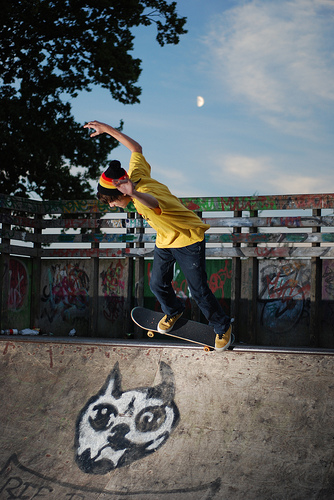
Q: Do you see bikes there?
A: No, there are no bikes.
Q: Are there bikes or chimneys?
A: No, there are no bikes or chimneys.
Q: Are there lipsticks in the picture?
A: No, there are no lipsticks.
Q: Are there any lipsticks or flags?
A: No, there are no lipsticks or flags.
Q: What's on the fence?
A: The graffiti is on the fence.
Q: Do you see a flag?
A: No, there are no flags.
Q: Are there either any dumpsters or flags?
A: No, there are no flags or dumpsters.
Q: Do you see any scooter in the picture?
A: No, there are no scooters.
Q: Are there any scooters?
A: No, there are no scooters.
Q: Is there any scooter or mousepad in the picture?
A: No, there are no scooters or mouse pads.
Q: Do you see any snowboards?
A: No, there are no snowboards.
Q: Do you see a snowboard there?
A: No, there are no snowboards.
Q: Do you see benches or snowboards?
A: No, there are no snowboards or benches.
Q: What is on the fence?
A: The graffiti is on the fence.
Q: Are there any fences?
A: Yes, there is a fence.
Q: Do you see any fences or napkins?
A: Yes, there is a fence.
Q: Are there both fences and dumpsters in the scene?
A: No, there is a fence but no dumpsters.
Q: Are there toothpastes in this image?
A: No, there are no toothpastes.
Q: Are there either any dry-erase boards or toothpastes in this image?
A: No, there are no toothpastes or dry-erase boards.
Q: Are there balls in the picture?
A: No, there are no balls.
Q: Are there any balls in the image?
A: No, there are no balls.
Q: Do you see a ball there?
A: No, there are no balls.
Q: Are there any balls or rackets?
A: No, there are no balls or rackets.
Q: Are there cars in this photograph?
A: No, there are no cars.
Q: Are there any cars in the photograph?
A: No, there are no cars.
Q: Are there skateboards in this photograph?
A: Yes, there is a skateboard.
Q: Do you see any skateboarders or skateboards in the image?
A: Yes, there is a skateboard.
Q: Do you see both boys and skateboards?
A: Yes, there are both a skateboard and a boy.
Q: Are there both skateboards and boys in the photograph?
A: Yes, there are both a skateboard and a boy.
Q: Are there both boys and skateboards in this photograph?
A: Yes, there are both a skateboard and a boy.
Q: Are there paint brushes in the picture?
A: No, there are no paint brushes.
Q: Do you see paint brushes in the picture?
A: No, there are no paint brushes.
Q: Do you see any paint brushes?
A: No, there are no paint brushes.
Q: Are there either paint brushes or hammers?
A: No, there are no paint brushes or hammers.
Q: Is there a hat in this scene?
A: Yes, there is a hat.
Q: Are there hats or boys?
A: Yes, there is a hat.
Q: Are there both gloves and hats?
A: No, there is a hat but no gloves.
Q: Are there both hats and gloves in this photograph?
A: No, there is a hat but no gloves.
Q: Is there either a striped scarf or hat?
A: Yes, there is a striped hat.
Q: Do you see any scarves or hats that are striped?
A: Yes, the hat is striped.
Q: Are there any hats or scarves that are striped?
A: Yes, the hat is striped.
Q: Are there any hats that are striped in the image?
A: Yes, there is a striped hat.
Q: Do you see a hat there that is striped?
A: Yes, there is a hat that is striped.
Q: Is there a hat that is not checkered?
A: Yes, there is a striped hat.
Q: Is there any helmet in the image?
A: No, there are no helmets.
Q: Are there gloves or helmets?
A: No, there are no helmets or gloves.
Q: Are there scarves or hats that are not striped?
A: No, there is a hat but it is striped.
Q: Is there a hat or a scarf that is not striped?
A: No, there is a hat but it is striped.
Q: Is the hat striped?
A: Yes, the hat is striped.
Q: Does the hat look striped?
A: Yes, the hat is striped.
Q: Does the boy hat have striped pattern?
A: Yes, the hat is striped.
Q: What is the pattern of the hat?
A: The hat is striped.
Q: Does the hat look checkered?
A: No, the hat is striped.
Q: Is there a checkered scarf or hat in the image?
A: No, there is a hat but it is striped.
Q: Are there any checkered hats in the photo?
A: No, there is a hat but it is striped.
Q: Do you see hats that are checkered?
A: No, there is a hat but it is striped.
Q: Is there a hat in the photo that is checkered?
A: No, there is a hat but it is striped.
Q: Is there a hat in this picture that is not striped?
A: No, there is a hat but it is striped.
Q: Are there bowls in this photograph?
A: No, there are no bowls.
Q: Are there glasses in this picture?
A: No, there are no glasses.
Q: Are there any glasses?
A: No, there are no glasses.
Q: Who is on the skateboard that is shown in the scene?
A: The boy is on the skateboard.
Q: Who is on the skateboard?
A: The boy is on the skateboard.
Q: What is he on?
A: The boy is on the skateboard.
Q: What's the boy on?
A: The boy is on the skateboard.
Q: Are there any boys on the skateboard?
A: Yes, there is a boy on the skateboard.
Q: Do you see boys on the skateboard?
A: Yes, there is a boy on the skateboard.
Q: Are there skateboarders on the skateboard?
A: No, there is a boy on the skateboard.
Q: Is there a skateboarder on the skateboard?
A: No, there is a boy on the skateboard.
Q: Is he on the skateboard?
A: Yes, the boy is on the skateboard.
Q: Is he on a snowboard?
A: No, the boy is on the skateboard.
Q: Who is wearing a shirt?
A: The boy is wearing a shirt.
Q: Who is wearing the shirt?
A: The boy is wearing a shirt.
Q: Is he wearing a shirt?
A: Yes, the boy is wearing a shirt.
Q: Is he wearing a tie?
A: No, the boy is wearing a shirt.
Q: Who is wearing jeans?
A: The boy is wearing jeans.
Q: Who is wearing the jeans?
A: The boy is wearing jeans.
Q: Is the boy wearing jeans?
A: Yes, the boy is wearing jeans.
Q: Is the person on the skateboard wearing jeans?
A: Yes, the boy is wearing jeans.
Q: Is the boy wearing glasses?
A: No, the boy is wearing jeans.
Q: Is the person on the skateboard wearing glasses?
A: No, the boy is wearing jeans.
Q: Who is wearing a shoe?
A: The boy is wearing a shoe.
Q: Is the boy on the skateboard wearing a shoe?
A: Yes, the boy is wearing a shoe.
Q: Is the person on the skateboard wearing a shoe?
A: Yes, the boy is wearing a shoe.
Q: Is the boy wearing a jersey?
A: No, the boy is wearing a shoe.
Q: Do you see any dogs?
A: Yes, there is a dog.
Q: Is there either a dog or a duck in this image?
A: Yes, there is a dog.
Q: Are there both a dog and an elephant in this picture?
A: No, there is a dog but no elephants.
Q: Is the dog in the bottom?
A: Yes, the dog is in the bottom of the image.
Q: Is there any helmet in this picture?
A: No, there are no helmets.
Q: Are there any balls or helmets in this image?
A: No, there are no helmets or balls.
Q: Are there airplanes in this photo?
A: No, there are no airplanes.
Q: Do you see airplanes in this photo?
A: No, there are no airplanes.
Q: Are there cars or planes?
A: No, there are no planes or cars.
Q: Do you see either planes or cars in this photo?
A: No, there are no planes or cars.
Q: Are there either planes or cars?
A: No, there are no planes or cars.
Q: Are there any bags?
A: No, there are no bags.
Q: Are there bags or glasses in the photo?
A: No, there are no bags or glasses.